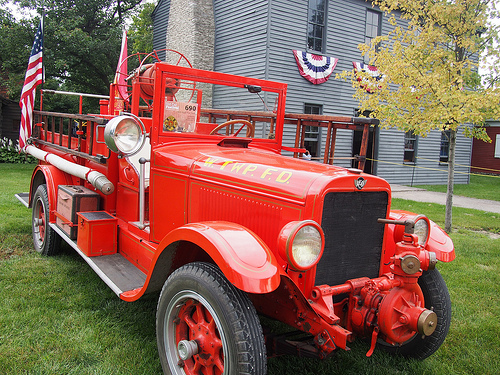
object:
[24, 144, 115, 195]
fire hose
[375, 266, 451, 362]
tire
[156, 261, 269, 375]
tire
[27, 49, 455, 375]
truck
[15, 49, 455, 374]
firetruck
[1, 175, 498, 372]
grass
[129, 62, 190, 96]
hose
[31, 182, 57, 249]
wheel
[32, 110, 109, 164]
ladder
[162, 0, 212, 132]
fire place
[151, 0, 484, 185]
building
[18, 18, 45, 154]
flag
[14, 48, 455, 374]
fire truck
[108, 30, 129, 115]
flag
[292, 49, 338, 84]
cloth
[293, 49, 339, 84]
banner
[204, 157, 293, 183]
letters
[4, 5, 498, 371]
outside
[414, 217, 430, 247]
light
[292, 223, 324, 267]
light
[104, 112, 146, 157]
light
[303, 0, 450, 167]
window